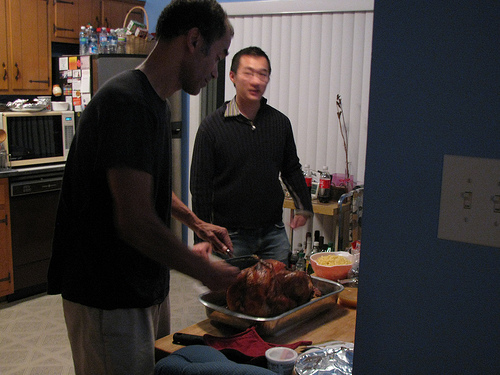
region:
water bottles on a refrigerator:
[71, 22, 125, 56]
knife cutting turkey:
[218, 237, 284, 284]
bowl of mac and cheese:
[309, 248, 355, 277]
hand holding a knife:
[196, 217, 274, 272]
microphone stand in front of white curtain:
[324, 88, 361, 178]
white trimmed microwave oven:
[2, 104, 87, 170]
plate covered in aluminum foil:
[293, 330, 345, 372]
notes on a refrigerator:
[57, 52, 97, 98]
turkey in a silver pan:
[216, 258, 347, 334]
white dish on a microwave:
[47, 96, 74, 114]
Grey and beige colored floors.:
[1, 266, 226, 366]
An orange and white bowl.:
[305, 247, 350, 274]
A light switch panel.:
[439, 152, 499, 247]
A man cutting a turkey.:
[53, 1, 345, 373]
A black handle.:
[172, 330, 204, 345]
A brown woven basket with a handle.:
[121, 5, 156, 57]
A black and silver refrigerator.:
[54, 57, 189, 258]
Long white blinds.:
[209, 9, 376, 205]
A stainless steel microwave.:
[2, 107, 79, 170]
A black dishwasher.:
[6, 178, 81, 296]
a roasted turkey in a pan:
[202, 247, 338, 326]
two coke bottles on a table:
[299, 158, 335, 205]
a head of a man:
[230, 42, 273, 104]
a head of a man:
[155, 2, 236, 99]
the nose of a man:
[246, 73, 266, 88]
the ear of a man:
[181, 22, 207, 57]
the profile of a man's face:
[192, 35, 234, 101]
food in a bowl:
[309, 247, 351, 277]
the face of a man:
[239, 58, 269, 101]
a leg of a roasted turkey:
[280, 243, 317, 301]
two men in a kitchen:
[50, 1, 312, 373]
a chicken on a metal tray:
[201, 255, 343, 337]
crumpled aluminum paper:
[296, 339, 353, 373]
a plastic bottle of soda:
[318, 165, 332, 202]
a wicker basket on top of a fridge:
[121, 7, 151, 54]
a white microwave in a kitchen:
[0, 110, 76, 167]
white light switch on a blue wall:
[438, 154, 498, 253]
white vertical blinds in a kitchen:
[224, 16, 363, 258]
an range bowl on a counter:
[309, 248, 351, 282]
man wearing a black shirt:
[48, 67, 170, 307]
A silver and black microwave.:
[2, 109, 75, 168]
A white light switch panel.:
[436, 153, 498, 249]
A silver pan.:
[198, 265, 343, 336]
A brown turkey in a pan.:
[189, 252, 344, 339]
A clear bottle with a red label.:
[319, 164, 331, 203]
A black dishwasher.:
[10, 179, 74, 298]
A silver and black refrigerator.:
[95, 55, 185, 273]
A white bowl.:
[52, 100, 71, 110]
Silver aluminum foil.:
[296, 340, 358, 373]